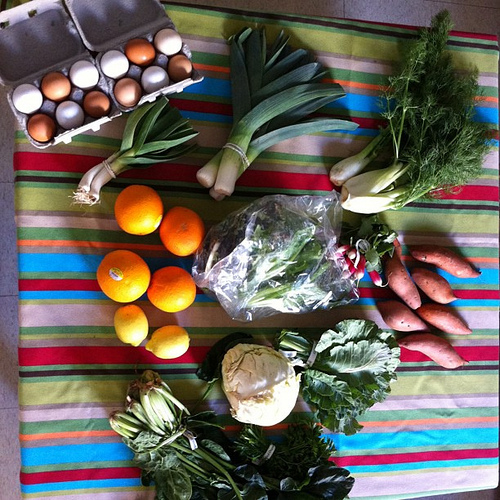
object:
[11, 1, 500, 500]
table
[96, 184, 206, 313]
oranges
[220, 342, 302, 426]
cabbage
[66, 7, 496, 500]
vegetables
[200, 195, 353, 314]
vegetables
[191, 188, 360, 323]
bag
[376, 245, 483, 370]
sweet potatoes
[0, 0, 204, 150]
carton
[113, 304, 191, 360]
lemons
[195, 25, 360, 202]
fennel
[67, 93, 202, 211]
leaks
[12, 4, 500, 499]
fabric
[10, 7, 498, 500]
food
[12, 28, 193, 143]
egges